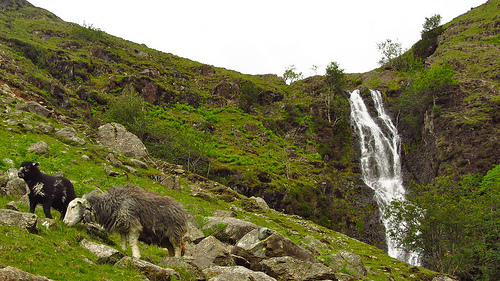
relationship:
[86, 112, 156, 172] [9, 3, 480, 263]
boulder on grass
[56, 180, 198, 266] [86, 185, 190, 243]
sheep has coat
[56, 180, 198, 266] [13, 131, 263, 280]
sheep on mountainside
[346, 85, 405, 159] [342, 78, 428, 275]
streams on waterfall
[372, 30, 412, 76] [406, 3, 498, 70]
bush near hilltop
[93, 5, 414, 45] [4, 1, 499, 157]
sky above hill